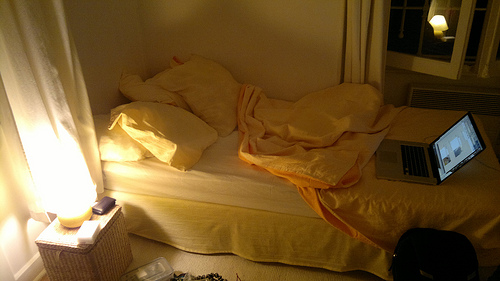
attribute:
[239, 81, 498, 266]
sheet — yellow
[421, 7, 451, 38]
light — one, illuminated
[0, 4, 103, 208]
curtain — white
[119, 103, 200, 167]
pillow — yellow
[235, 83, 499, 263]
bedding — yellow, white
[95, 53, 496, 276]
bed — one, unmade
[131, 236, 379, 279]
floor — white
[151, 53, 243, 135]
pillows — yellow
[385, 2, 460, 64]
window — one, open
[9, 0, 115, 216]
curtain — white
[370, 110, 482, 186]
laptop — sitting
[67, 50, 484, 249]
bedroom area — messy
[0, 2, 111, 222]
curtain — white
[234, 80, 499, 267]
blanket — one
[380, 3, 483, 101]
window — open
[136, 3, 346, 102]
wall — white, behind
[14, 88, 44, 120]
fabric — white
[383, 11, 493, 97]
window — one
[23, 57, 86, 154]
fabric — white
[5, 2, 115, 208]
fabric — white